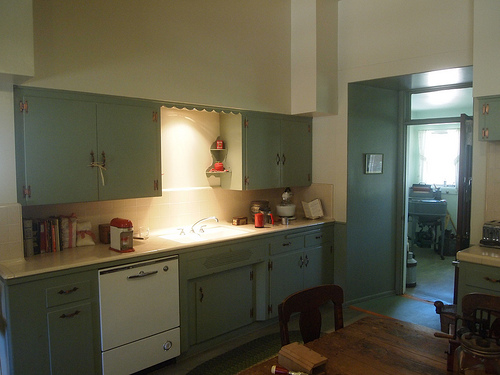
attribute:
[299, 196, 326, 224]
book — open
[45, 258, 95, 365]
cabinet — kitchen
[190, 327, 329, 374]
rug — blue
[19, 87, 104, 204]
cabinet — kitchen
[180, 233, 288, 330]
cabinet — kitchen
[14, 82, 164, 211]
cabinet — green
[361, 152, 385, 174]
photo — white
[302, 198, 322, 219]
book — open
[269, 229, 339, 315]
drawer — kitchen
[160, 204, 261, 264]
water faucet. — silver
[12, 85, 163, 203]
cabinet — green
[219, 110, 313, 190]
cabinet — green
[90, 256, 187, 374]
cabinet — kitchen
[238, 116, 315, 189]
cabinet — above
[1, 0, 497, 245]
wall — white